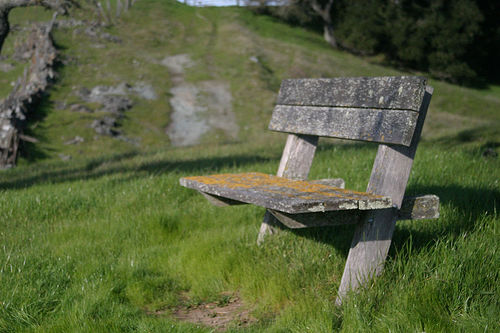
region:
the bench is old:
[206, 69, 391, 247]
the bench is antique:
[194, 83, 457, 283]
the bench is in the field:
[189, 74, 462, 296]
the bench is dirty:
[169, 68, 468, 273]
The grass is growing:
[11, 10, 486, 316]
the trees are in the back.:
[286, 5, 476, 80]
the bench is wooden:
[165, 77, 428, 257]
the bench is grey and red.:
[188, 63, 444, 264]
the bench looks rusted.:
[145, 73, 460, 298]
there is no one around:
[15, 9, 480, 324]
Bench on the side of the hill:
[172, 71, 437, 314]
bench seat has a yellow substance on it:
[178, 165, 398, 239]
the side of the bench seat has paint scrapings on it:
[289, 198, 394, 213]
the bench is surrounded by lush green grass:
[4, 158, 499, 328]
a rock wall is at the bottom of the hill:
[4, 5, 75, 158]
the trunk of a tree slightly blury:
[300, 3, 350, 52]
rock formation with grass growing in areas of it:
[161, 55, 247, 145]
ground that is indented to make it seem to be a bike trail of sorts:
[194, 5, 222, 76]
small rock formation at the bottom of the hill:
[87, 91, 132, 137]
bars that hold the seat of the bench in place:
[276, 198, 438, 234]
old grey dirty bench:
[232, 86, 455, 307]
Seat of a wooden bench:
[178, 170, 395, 213]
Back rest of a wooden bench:
[266, 80, 426, 145]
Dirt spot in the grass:
[138, 288, 265, 331]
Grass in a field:
[10, 256, 140, 330]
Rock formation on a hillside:
[13, 20, 48, 151]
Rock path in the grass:
[165, 48, 230, 137]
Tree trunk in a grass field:
[310, 1, 337, 47]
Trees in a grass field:
[339, 2, 487, 78]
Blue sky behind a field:
[184, 0, 256, 9]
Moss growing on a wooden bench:
[184, 167, 297, 188]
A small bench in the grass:
[175, 64, 455, 322]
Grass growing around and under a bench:
[175, 67, 447, 303]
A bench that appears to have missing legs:
[167, 63, 476, 305]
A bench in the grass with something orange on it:
[165, 65, 450, 305]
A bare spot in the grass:
[140, 265, 285, 325]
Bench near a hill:
[10, 5, 455, 300]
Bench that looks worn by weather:
[172, 55, 443, 305]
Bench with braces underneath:
[161, 61, 456, 306]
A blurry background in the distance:
[15, 10, 470, 300]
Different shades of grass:
[10, 162, 487, 322]